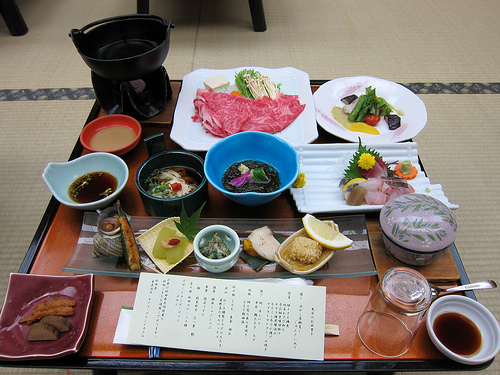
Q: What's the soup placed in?
A: Bowl.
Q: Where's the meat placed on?
A: Plate.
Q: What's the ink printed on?
A: Paper.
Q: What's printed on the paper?
A: Black ink.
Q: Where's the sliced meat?
A: On square plate.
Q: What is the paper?
A: Bill.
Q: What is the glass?
A: Clear.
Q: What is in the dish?
A: Food.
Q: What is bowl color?
A: Blue.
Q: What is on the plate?
A: Vegetables.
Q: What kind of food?
A: Asian.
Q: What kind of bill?
A: Printed.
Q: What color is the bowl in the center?
A: Blue.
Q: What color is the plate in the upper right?
A: White.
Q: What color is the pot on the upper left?
A: Black.